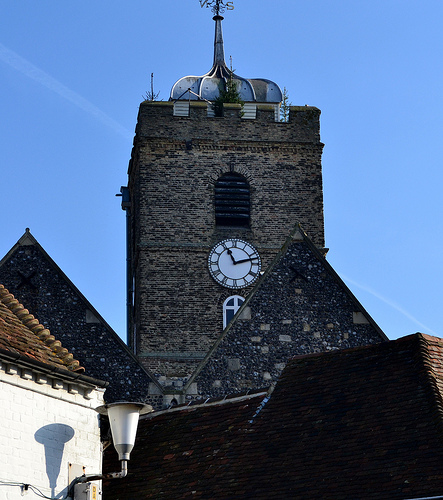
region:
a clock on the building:
[207, 233, 262, 288]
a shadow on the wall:
[28, 424, 73, 488]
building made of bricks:
[9, 395, 32, 430]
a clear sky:
[351, 178, 397, 234]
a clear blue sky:
[355, 191, 410, 255]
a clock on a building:
[212, 236, 257, 285]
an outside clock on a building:
[206, 235, 265, 297]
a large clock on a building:
[198, 242, 285, 292]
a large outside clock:
[198, 236, 269, 294]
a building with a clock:
[201, 236, 259, 285]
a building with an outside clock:
[194, 231, 278, 301]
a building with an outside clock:
[203, 233, 271, 283]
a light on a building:
[70, 384, 164, 478]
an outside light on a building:
[85, 398, 171, 482]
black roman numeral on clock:
[230, 238, 238, 248]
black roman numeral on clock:
[240, 243, 246, 252]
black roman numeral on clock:
[247, 250, 256, 257]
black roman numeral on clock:
[249, 260, 261, 266]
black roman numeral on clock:
[241, 274, 247, 285]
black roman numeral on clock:
[230, 278, 239, 288]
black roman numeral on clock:
[221, 274, 229, 286]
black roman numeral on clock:
[211, 267, 221, 279]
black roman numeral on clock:
[209, 259, 218, 267]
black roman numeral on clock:
[212, 248, 221, 257]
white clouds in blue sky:
[317, 67, 361, 103]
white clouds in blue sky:
[365, 143, 420, 196]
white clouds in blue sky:
[2, 14, 67, 65]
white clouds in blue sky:
[350, 114, 394, 155]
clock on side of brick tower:
[210, 236, 259, 291]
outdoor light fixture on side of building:
[93, 395, 150, 473]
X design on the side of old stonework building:
[286, 260, 311, 285]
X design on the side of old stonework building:
[14, 268, 36, 293]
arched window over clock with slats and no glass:
[209, 162, 255, 232]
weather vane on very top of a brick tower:
[194, 0, 241, 18]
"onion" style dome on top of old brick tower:
[169, 18, 280, 100]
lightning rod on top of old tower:
[141, 69, 162, 101]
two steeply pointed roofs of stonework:
[0, 225, 391, 392]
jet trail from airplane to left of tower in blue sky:
[1, 46, 131, 153]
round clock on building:
[186, 199, 296, 294]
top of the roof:
[236, 325, 435, 416]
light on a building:
[74, 367, 168, 489]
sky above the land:
[24, 24, 129, 158]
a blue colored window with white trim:
[220, 294, 245, 332]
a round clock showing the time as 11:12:
[205, 237, 263, 289]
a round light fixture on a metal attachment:
[74, 400, 155, 484]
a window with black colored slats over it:
[212, 170, 253, 230]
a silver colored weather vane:
[169, 0, 286, 100]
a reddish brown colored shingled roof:
[104, 333, 441, 499]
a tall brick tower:
[128, 99, 322, 404]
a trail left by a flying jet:
[1, 45, 132, 144]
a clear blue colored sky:
[2, 0, 442, 343]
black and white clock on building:
[203, 234, 264, 293]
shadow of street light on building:
[31, 419, 80, 498]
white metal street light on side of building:
[90, 397, 158, 464]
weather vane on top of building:
[193, 1, 237, 75]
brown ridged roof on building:
[0, 282, 112, 385]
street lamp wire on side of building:
[0, 478, 73, 498]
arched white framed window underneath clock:
[218, 291, 255, 331]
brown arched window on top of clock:
[207, 167, 255, 232]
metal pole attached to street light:
[66, 460, 129, 497]